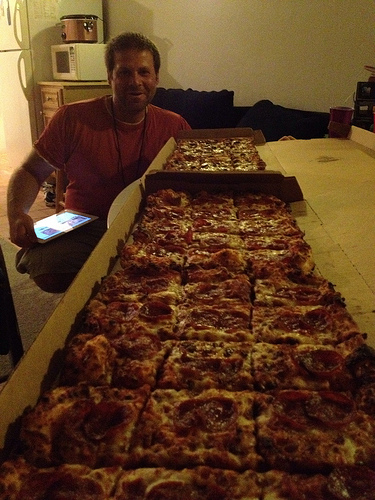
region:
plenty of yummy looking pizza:
[9, 42, 373, 498]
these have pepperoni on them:
[97, 328, 258, 407]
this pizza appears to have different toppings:
[181, 136, 258, 176]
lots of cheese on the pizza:
[139, 338, 252, 393]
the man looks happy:
[87, 22, 175, 121]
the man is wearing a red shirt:
[30, 96, 199, 233]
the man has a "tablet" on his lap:
[13, 200, 98, 251]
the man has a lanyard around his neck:
[106, 83, 183, 224]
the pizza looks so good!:
[160, 208, 274, 463]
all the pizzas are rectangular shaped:
[49, 189, 362, 483]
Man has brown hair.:
[96, 9, 217, 79]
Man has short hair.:
[99, 24, 180, 82]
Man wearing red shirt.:
[73, 126, 133, 174]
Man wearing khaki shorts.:
[40, 226, 108, 268]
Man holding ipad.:
[23, 178, 116, 280]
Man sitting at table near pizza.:
[70, 58, 184, 185]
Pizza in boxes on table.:
[150, 113, 261, 492]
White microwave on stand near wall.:
[41, 41, 126, 111]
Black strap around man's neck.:
[99, 102, 162, 199]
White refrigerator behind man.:
[6, 13, 72, 137]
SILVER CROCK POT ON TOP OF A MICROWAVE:
[57, 14, 99, 44]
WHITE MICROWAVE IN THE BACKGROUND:
[49, 43, 113, 83]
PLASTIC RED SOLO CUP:
[328, 103, 354, 142]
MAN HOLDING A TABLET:
[3, 32, 200, 298]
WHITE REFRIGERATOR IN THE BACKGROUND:
[0, 0, 107, 174]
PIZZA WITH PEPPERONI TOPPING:
[0, 130, 373, 499]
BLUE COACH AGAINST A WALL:
[134, 86, 351, 155]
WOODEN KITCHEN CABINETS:
[37, 81, 120, 190]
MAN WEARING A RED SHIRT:
[4, 31, 207, 295]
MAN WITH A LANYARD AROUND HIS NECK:
[2, 26, 199, 298]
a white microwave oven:
[44, 40, 108, 82]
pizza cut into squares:
[59, 330, 345, 497]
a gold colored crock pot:
[53, 11, 101, 44]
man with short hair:
[96, 30, 170, 120]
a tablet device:
[8, 203, 104, 245]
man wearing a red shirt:
[18, 24, 195, 232]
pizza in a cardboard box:
[163, 122, 336, 217]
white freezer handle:
[0, 0, 43, 51]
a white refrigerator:
[1, 0, 104, 133]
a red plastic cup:
[317, 97, 373, 134]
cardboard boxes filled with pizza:
[0, 123, 374, 498]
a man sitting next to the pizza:
[7, 30, 297, 294]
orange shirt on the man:
[31, 92, 193, 216]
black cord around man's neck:
[107, 94, 147, 185]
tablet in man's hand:
[34, 207, 99, 242]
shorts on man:
[14, 218, 108, 278]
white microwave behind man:
[49, 40, 109, 80]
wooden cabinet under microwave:
[36, 77, 115, 131]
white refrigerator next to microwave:
[0, 0, 108, 182]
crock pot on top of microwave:
[57, 12, 98, 40]